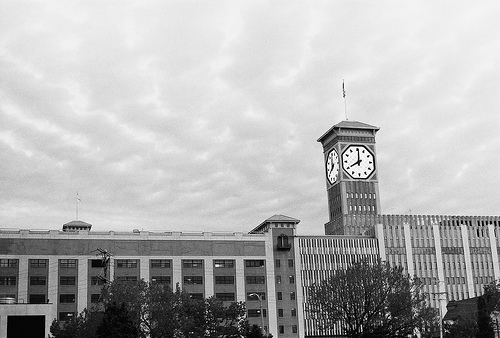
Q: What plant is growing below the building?
A: Trees.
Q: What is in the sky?
A: Clouds.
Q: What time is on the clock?
A: 8:00.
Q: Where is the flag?
A: On the building.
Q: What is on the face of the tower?
A: Clock.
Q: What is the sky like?
A: Overcast.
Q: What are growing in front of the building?
A: Trees.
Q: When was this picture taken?
A: 8:00.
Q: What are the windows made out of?
A: Glass.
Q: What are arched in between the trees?
A: Street lights.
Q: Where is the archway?
A: Lower left of the building.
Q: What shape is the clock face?
A: Octagon.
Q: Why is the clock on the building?
A: To show time.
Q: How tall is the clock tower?
A: Taller than the building.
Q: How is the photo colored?
A: Black and white.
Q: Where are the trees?
A: In front of the building.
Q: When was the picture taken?
A: 8:00.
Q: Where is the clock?
A: On the tower.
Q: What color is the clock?
A: White.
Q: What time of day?
A: Daytime.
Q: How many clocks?
A: 2.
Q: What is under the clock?
A: A building.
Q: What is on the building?
A: Windows.